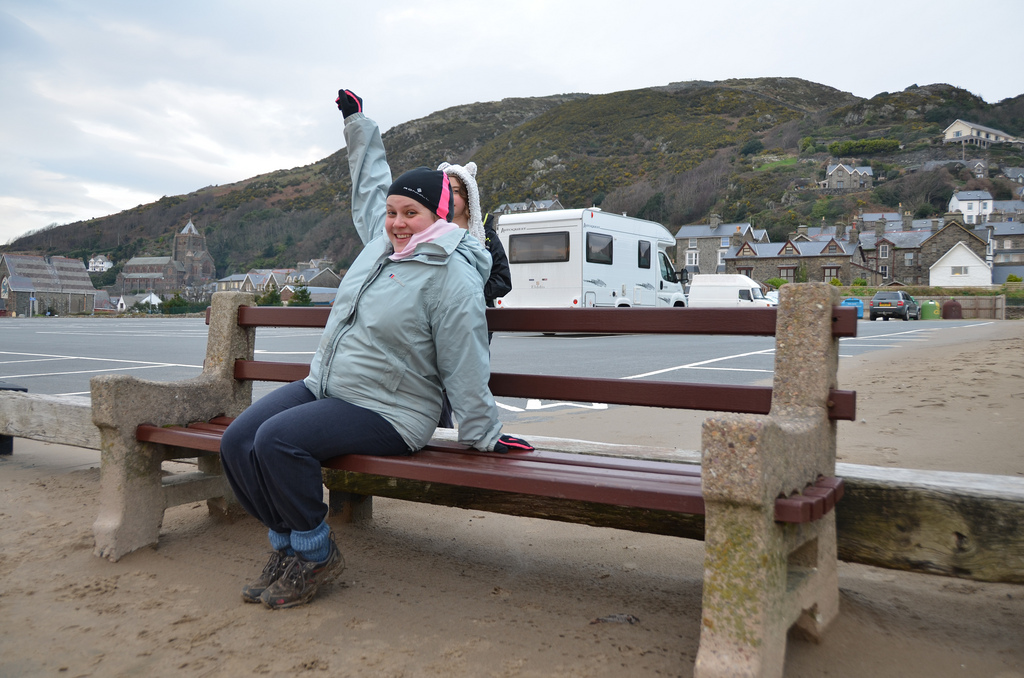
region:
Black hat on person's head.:
[388, 155, 458, 216]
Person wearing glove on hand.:
[493, 426, 541, 465]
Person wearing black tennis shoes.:
[243, 528, 338, 618]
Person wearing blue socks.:
[255, 525, 354, 576]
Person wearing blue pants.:
[228, 385, 342, 509]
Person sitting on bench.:
[186, 334, 491, 490]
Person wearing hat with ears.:
[432, 149, 497, 222]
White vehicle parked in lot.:
[508, 211, 671, 294]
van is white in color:
[498, 191, 695, 306]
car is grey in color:
[865, 283, 932, 323]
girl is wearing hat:
[390, 172, 455, 218]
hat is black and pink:
[378, 160, 456, 218]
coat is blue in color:
[296, 73, 530, 467]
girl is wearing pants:
[216, 348, 426, 551]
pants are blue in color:
[217, 349, 405, 550]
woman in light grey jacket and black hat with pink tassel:
[214, 86, 540, 606]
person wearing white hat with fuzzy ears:
[432, 159, 512, 347]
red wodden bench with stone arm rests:
[94, 282, 862, 675]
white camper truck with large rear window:
[488, 208, 692, 338]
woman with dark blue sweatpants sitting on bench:
[214, 85, 540, 607]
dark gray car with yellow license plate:
[867, 285, 921, 323]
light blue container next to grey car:
[837, 297, 863, 316]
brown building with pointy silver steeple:
[115, 218, 214, 294]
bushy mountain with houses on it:
[593, 83, 1023, 240]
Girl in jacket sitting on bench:
[214, 85, 537, 610]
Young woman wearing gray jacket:
[211, 85, 535, 613]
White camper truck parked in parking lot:
[489, 205, 689, 308]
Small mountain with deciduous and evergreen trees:
[0, 75, 1023, 271]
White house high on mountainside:
[938, 114, 1019, 146]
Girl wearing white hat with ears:
[438, 158, 511, 345]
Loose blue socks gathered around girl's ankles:
[263, 514, 333, 559]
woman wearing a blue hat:
[375, 165, 465, 226]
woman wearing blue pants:
[201, 369, 386, 525]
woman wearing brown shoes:
[224, 527, 354, 633]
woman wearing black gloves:
[473, 411, 537, 470]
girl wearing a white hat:
[427, 154, 503, 246]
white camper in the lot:
[486, 200, 689, 324]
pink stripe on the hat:
[424, 165, 464, 219]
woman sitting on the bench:
[233, 82, 534, 602]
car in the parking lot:
[860, 274, 922, 329]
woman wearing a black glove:
[319, 79, 384, 134]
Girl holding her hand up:
[212, 83, 530, 609]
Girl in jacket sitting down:
[217, 85, 541, 611]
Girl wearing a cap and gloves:
[214, 83, 538, 609]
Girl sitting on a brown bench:
[91, 88, 854, 676]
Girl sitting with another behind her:
[206, 79, 542, 608]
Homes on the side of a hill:
[676, 77, 1022, 287]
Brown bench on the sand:
[85, 291, 854, 675]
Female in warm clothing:
[220, 80, 538, 606]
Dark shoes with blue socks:
[243, 524, 342, 611]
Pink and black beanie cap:
[388, 162, 455, 219]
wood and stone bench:
[73, 274, 871, 671]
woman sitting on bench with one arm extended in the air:
[210, 82, 540, 618]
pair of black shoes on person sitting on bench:
[235, 537, 354, 617]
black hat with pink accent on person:
[383, 161, 457, 229]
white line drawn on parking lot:
[1, 344, 208, 406]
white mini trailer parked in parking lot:
[491, 197, 694, 322]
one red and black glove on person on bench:
[327, 79, 366, 122]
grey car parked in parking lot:
[860, 278, 921, 330]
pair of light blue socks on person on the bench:
[253, 509, 339, 573]